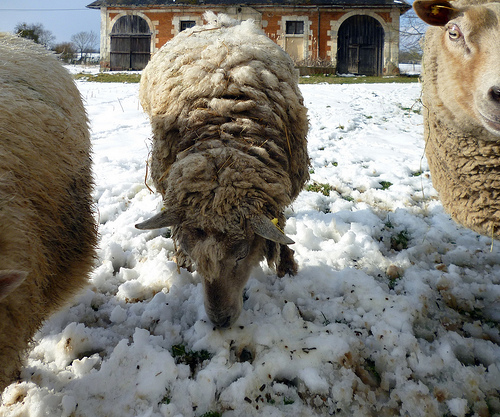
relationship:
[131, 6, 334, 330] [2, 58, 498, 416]
sheep on snow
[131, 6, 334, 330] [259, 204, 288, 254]
sheep has ear tag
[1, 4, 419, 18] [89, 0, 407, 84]
power line behind building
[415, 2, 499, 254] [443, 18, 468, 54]
sheep has eye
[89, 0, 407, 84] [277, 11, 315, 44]
building has window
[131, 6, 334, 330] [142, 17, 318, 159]
sheep has back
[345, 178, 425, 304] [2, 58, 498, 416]
sheep tracks in snow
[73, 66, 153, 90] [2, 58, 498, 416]
grass poking through snow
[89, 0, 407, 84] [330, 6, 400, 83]
building has doorway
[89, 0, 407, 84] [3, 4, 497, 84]
building in back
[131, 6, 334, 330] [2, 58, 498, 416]
sheep in snow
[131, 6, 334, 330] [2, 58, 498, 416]
sheep eating snow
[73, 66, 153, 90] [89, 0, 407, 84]
grass in front of building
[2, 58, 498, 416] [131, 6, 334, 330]
snow under sheep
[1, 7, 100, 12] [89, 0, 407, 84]
power line near building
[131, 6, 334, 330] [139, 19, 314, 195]
sheep has wool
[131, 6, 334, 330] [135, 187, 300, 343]
sheep has head